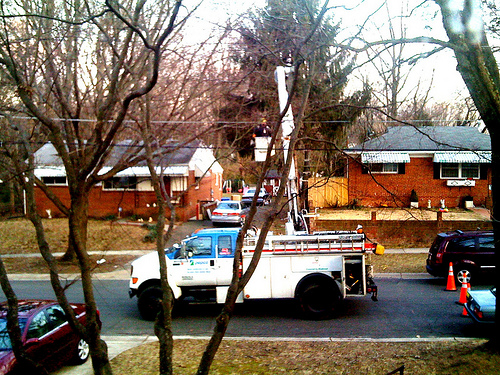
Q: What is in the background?
A: A red brick house.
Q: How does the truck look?
A: It is white and blue.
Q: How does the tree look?
A: It has no leaves.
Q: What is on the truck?
A: A white crane.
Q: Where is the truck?
A: On the road.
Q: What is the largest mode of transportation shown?
A: Truck.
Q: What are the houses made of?
A: Red brick.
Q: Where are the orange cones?
A: Behind the truck.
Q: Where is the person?
A: In the bucket on the boom.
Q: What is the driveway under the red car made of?
A: Concrete.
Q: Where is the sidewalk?
A: In front of the brick houses.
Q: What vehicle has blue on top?
A: Truck.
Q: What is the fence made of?
A: Wood.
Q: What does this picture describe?
A: People working on power lines.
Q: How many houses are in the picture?
A: Two.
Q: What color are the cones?
A: Orange.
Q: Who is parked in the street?
A: The electric company truck.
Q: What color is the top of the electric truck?
A: Blue.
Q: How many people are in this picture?
A: One.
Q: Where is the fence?
A: On side of the house.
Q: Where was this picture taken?
A: On a residential street.